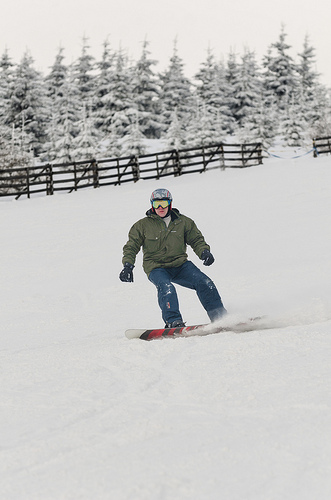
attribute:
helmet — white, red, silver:
[129, 186, 178, 200]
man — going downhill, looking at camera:
[118, 186, 242, 356]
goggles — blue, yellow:
[154, 197, 178, 203]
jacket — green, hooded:
[135, 212, 201, 265]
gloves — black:
[202, 249, 219, 278]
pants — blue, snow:
[149, 267, 232, 314]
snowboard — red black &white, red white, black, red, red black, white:
[130, 315, 280, 339]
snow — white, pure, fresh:
[180, 451, 302, 483]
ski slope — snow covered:
[16, 275, 89, 326]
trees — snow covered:
[11, 58, 330, 120]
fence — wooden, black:
[89, 164, 185, 180]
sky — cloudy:
[236, 9, 287, 14]